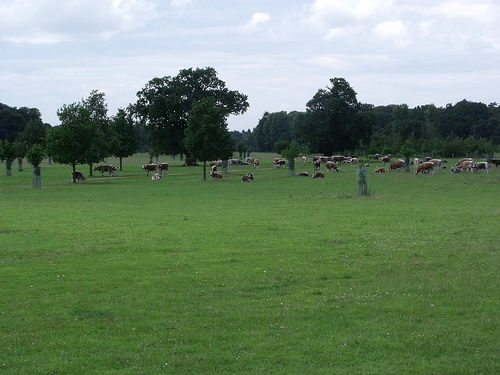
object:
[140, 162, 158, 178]
cow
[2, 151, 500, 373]
field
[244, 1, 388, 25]
cloud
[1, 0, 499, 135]
sky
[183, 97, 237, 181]
tree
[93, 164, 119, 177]
cow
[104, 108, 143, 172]
tree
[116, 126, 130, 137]
leaves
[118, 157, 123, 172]
trunk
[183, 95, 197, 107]
leaves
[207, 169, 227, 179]
cow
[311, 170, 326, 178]
animal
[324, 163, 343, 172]
animal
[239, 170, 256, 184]
animal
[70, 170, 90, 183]
cow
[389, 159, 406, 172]
cow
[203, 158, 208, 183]
trunk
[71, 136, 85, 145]
leaves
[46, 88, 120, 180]
tree